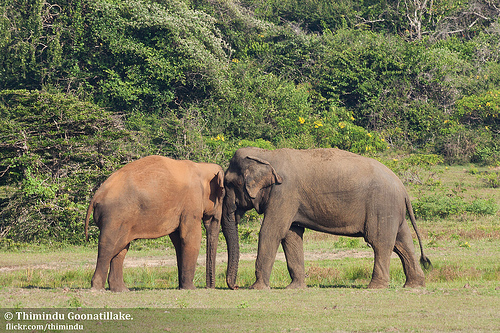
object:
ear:
[241, 154, 283, 199]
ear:
[217, 171, 226, 197]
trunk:
[205, 216, 221, 289]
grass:
[1, 284, 499, 331]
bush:
[189, 66, 400, 146]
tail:
[403, 190, 436, 274]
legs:
[178, 213, 202, 290]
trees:
[396, 0, 490, 36]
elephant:
[221, 147, 433, 290]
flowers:
[367, 132, 372, 137]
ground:
[328, 75, 411, 105]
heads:
[224, 147, 263, 224]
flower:
[313, 120, 323, 128]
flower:
[297, 116, 305, 125]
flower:
[338, 122, 345, 129]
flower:
[365, 146, 372, 151]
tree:
[198, 57, 387, 156]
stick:
[95, 114, 163, 149]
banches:
[367, 0, 500, 45]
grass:
[313, 263, 361, 284]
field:
[4, 163, 500, 331]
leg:
[392, 218, 425, 283]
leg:
[364, 208, 399, 283]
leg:
[281, 222, 306, 282]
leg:
[255, 184, 299, 284]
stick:
[61, 164, 109, 176]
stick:
[17, 125, 31, 152]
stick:
[50, 118, 62, 130]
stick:
[85, 104, 125, 135]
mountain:
[3, 0, 498, 236]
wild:
[0, 0, 497, 333]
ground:
[0, 162, 500, 333]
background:
[3, 0, 495, 333]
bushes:
[5, 72, 111, 160]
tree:
[2, 0, 234, 119]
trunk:
[221, 207, 240, 290]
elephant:
[83, 154, 226, 293]